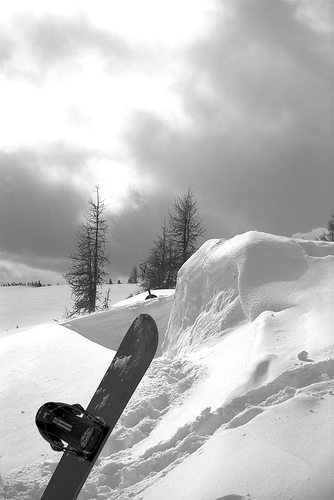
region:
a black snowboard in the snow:
[38, 313, 159, 499]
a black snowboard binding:
[33, 402, 111, 449]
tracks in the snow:
[112, 363, 330, 497]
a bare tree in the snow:
[71, 219, 98, 312]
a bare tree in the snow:
[80, 182, 107, 309]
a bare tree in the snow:
[150, 215, 173, 288]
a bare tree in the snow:
[165, 184, 199, 275]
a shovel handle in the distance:
[139, 260, 157, 300]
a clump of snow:
[297, 348, 309, 360]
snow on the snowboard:
[111, 350, 130, 367]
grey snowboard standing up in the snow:
[40, 312, 158, 498]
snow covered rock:
[174, 228, 319, 329]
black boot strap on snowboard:
[34, 398, 107, 457]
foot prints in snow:
[103, 368, 331, 488]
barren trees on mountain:
[64, 182, 111, 317]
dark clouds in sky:
[117, 101, 284, 218]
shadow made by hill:
[66, 302, 175, 362]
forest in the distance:
[3, 279, 44, 288]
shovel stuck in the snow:
[136, 259, 158, 305]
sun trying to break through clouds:
[30, 30, 167, 127]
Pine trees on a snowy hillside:
[63, 184, 207, 316]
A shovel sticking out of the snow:
[135, 260, 157, 300]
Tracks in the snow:
[149, 358, 330, 437]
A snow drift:
[170, 231, 311, 342]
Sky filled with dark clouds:
[6, 9, 331, 233]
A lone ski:
[40, 315, 161, 493]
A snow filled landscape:
[3, 229, 331, 477]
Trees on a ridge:
[1, 277, 63, 292]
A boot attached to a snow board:
[35, 314, 122, 496]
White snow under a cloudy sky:
[5, 196, 333, 352]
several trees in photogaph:
[77, 186, 208, 313]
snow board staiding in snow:
[28, 287, 184, 489]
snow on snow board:
[93, 330, 158, 412]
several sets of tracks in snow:
[95, 335, 330, 483]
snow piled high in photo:
[179, 239, 293, 336]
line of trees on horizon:
[0, 256, 174, 300]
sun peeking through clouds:
[10, 46, 165, 235]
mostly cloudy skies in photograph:
[4, 43, 327, 249]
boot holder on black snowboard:
[24, 376, 131, 457]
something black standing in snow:
[128, 261, 175, 306]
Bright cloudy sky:
[1, 0, 332, 284]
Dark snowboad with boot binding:
[16, 311, 159, 498]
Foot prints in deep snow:
[81, 341, 332, 496]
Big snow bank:
[149, 230, 333, 386]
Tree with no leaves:
[63, 181, 111, 316]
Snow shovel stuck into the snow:
[139, 259, 154, 300]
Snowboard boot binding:
[33, 399, 110, 459]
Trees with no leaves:
[63, 182, 205, 318]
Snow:
[1, 236, 331, 489]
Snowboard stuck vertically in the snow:
[31, 312, 164, 498]